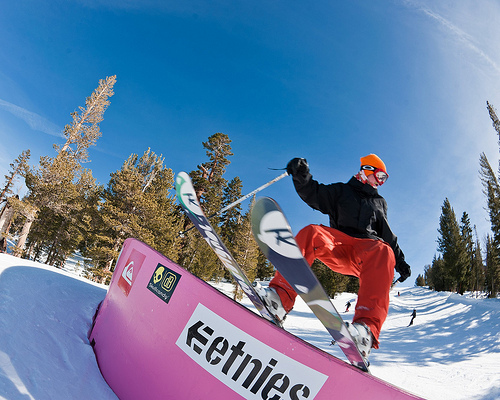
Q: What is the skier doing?
A: Riding a rail.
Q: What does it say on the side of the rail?
A: Etnies.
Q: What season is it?
A: Winter.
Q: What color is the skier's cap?
A: Orange.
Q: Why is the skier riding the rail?
A: To have fun.